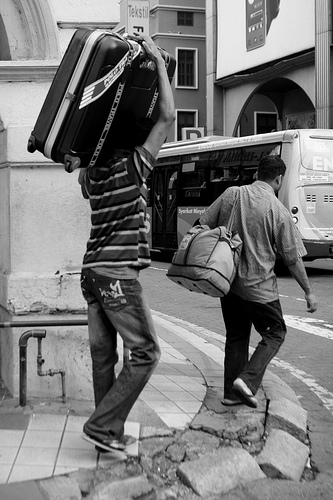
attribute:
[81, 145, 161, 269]
shirt — striped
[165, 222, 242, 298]
bag — light carried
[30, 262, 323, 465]
sidewalk — brick, crumbling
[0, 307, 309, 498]
sidewalk — broken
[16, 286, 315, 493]
sidewalk — tiled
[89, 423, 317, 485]
curb — crumbled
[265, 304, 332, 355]
line — white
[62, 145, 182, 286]
shirt — tri-colored, striped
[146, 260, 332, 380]
road — brick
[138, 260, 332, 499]
street — city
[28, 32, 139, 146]
suitcase — large, dark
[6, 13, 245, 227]
suitcase — large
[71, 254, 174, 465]
pants — dark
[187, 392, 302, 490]
curb — crumbled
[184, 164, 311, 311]
shirt — loose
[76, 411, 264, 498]
rocks — crumbled